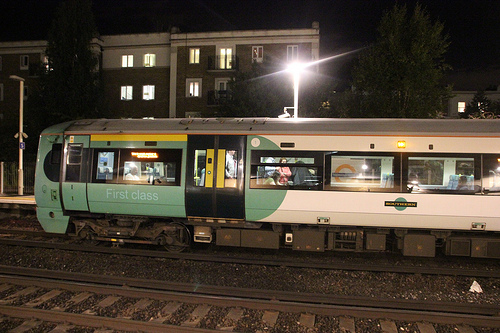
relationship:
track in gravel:
[0, 264, 500, 333] [3, 204, 498, 329]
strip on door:
[203, 147, 225, 189] [181, 131, 247, 219]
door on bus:
[181, 131, 247, 219] [33, 117, 499, 260]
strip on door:
[203, 147, 225, 187] [185, 133, 247, 219]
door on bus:
[185, 133, 247, 219] [33, 117, 499, 260]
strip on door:
[74, 123, 202, 163] [185, 133, 247, 219]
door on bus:
[185, 133, 247, 219] [45, 107, 492, 224]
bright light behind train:
[253, 42, 370, 102] [23, 102, 490, 252]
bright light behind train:
[250, 42, 370, 102] [35, 116, 497, 266]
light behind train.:
[252, 52, 346, 114] [43, 107, 498, 262]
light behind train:
[252, 52, 346, 114] [26, 106, 496, 291]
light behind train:
[252, 52, 346, 114] [35, 116, 497, 266]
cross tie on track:
[255, 309, 278, 333] [1, 273, 498, 330]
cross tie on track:
[178, 302, 213, 328] [185, 300, 205, 320]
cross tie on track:
[115, 295, 154, 320] [105, 294, 160, 323]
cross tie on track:
[379, 317, 399, 331] [1, 266, 498, 331]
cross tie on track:
[414, 318, 439, 330] [1, 266, 498, 331]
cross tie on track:
[337, 315, 357, 331] [1, 266, 498, 331]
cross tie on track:
[300, 312, 314, 330] [1, 266, 498, 331]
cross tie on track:
[261, 309, 278, 331] [1, 266, 498, 331]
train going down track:
[29, 96, 499, 280] [2, 220, 482, 286]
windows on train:
[65, 143, 484, 191] [23, 102, 490, 252]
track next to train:
[4, 232, 492, 332] [23, 102, 490, 252]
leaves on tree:
[395, 12, 445, 62] [347, 1, 450, 123]